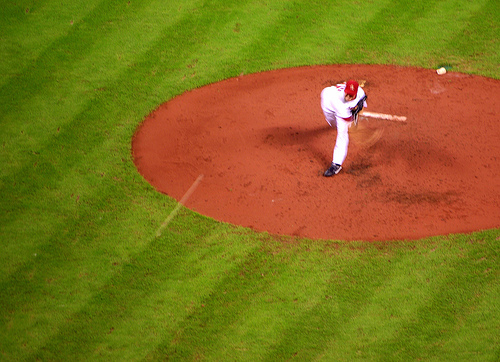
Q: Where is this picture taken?
A: A Baseball field.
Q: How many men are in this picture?
A: One.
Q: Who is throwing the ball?
A: The Pitcher.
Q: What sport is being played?
A: Baseball.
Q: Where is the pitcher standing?
A: The Pitcher's Mound.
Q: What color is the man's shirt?
A: White.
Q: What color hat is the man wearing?
A: Red.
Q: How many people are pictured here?
A: One.